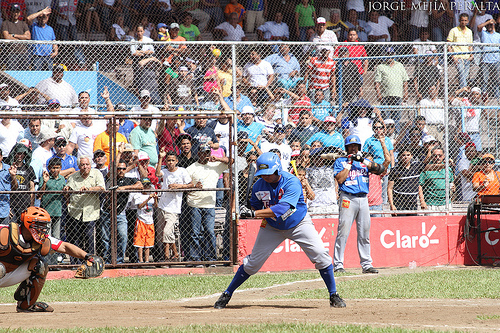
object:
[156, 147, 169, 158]
hand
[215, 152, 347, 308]
batter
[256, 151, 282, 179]
helmet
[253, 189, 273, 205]
logo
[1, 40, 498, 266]
fence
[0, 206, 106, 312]
catcher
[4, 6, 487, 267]
audience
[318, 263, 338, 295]
socks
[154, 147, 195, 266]
boy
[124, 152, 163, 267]
man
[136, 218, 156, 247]
shorts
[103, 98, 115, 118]
his arm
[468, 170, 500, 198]
shirt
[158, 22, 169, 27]
hat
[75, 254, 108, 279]
glove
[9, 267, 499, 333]
dirt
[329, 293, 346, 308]
shoe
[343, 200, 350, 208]
sign